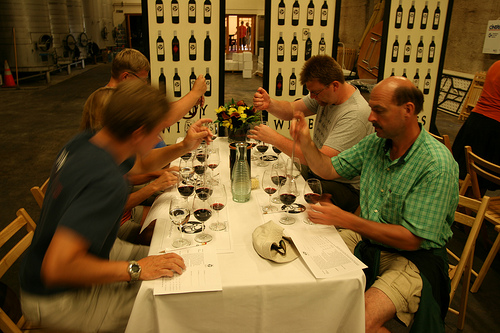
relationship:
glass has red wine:
[302, 177, 325, 226] [303, 191, 322, 204]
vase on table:
[224, 135, 260, 206] [120, 130, 371, 333]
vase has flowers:
[224, 135, 260, 206] [214, 100, 260, 142]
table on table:
[120, 130, 371, 333] [120, 130, 371, 333]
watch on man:
[127, 255, 141, 285] [17, 73, 192, 333]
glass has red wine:
[189, 190, 217, 247] [303, 191, 322, 204]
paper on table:
[280, 220, 371, 288] [120, 130, 371, 333]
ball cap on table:
[251, 218, 305, 265] [120, 130, 371, 333]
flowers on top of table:
[214, 100, 260, 142] [120, 130, 371, 333]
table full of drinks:
[120, 130, 371, 333] [171, 141, 232, 252]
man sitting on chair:
[289, 70, 464, 332] [450, 180, 484, 330]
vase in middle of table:
[224, 135, 260, 206] [120, 130, 371, 333]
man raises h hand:
[100, 43, 208, 156] [173, 66, 209, 124]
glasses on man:
[299, 77, 332, 103] [243, 50, 382, 216]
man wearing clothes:
[289, 70, 464, 332] [347, 131, 455, 319]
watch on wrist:
[127, 255, 141, 285] [121, 250, 155, 297]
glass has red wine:
[275, 176, 300, 226] [303, 191, 322, 204]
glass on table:
[166, 193, 198, 249] [120, 130, 371, 333]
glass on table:
[189, 190, 217, 247] [120, 130, 371, 333]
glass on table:
[259, 166, 281, 216] [120, 130, 371, 333]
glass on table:
[275, 176, 300, 226] [120, 130, 371, 333]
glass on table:
[302, 177, 325, 226] [120, 130, 371, 333]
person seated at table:
[289, 70, 464, 332] [120, 130, 371, 333]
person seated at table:
[243, 50, 382, 216] [120, 130, 371, 333]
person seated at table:
[100, 43, 208, 156] [120, 130, 371, 333]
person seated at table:
[17, 73, 192, 333] [120, 130, 371, 333]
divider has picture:
[141, 0, 231, 153] [154, 26, 168, 64]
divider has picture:
[141, 0, 231, 153] [171, 26, 183, 63]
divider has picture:
[141, 0, 231, 153] [186, 28, 200, 63]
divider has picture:
[141, 0, 231, 153] [203, 28, 214, 63]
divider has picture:
[141, 0, 231, 153] [152, 0, 167, 26]